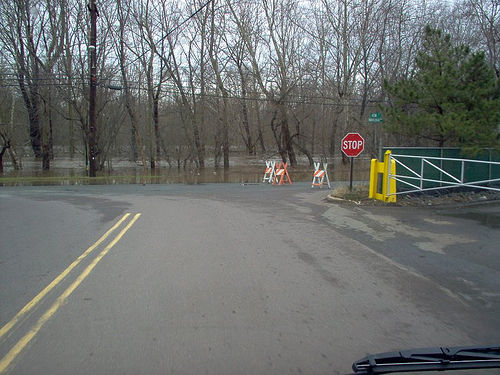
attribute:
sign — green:
[365, 115, 385, 125]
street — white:
[2, 189, 499, 369]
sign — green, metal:
[366, 112, 387, 122]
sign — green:
[341, 107, 401, 134]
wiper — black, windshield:
[353, 344, 498, 373]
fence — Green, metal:
[375, 142, 497, 184]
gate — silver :
[382, 152, 497, 199]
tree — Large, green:
[372, 22, 498, 149]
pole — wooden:
[78, 2, 104, 177]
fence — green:
[382, 144, 498, 199]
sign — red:
[338, 127, 365, 152]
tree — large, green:
[383, 24, 498, 168]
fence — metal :
[203, 122, 493, 219]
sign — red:
[337, 130, 368, 160]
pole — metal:
[348, 154, 358, 188]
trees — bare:
[84, 0, 284, 178]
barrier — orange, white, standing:
[309, 162, 330, 188]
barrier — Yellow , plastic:
[356, 141, 401, 208]